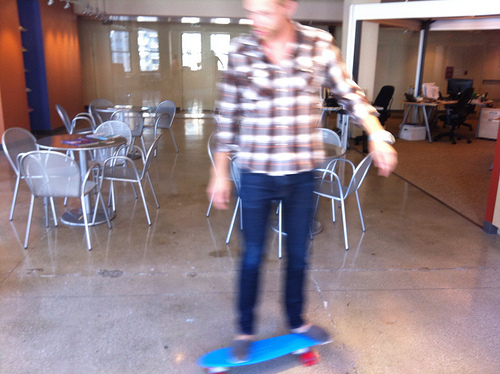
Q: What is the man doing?
A: Skating.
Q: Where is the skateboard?
A: On the ground.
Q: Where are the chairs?
A: Next to the tables.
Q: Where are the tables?
A: In the dining area.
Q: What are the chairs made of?
A: Metal.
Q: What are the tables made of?
A: Metal.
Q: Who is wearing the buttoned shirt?
A: The skater.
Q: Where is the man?
A: In front of the tables.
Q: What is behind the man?
A: Tables.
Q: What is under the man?
A: A skateboard.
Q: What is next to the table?
A: A silver chair.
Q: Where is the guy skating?
A: At a cafe area.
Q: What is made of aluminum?
A: The table and chairs.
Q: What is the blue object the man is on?
A: A skateboard.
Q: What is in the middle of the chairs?
A: A round metal table.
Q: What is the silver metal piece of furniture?
A: A chair.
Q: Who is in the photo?
A: A man.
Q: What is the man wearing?
A: Clothes.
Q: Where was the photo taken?
A: At a cafe.